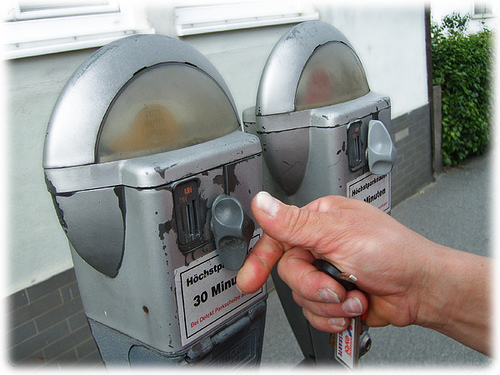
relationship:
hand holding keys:
[237, 188, 401, 335] [310, 254, 361, 366]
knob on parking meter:
[208, 190, 257, 269] [38, 32, 268, 366]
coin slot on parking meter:
[185, 195, 200, 243] [38, 32, 268, 366]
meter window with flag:
[92, 59, 241, 161] [105, 103, 186, 155]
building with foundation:
[13, 22, 452, 235] [11, 273, 93, 360]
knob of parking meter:
[208, 190, 257, 269] [64, 38, 277, 301]